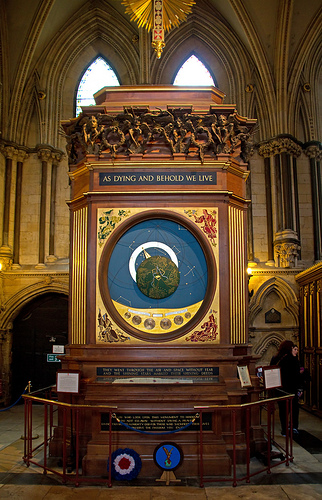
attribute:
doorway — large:
[5, 273, 82, 446]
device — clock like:
[89, 197, 237, 349]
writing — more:
[96, 364, 225, 384]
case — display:
[286, 259, 311, 431]